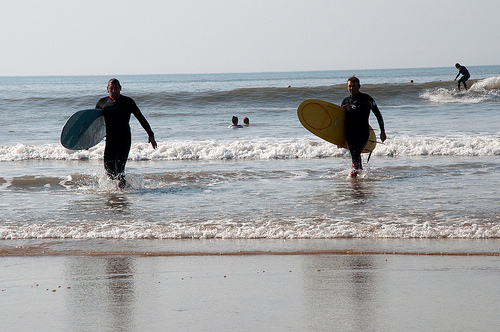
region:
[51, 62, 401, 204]
Two surfers holding their surfboards on the sea shore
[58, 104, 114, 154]
a blue surfboard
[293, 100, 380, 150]
a yellow surfboard with a red ring around it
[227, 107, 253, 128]
two people swimming in the ocean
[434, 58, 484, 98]
a surfer in the ocean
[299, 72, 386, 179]
a man in a wetsuit holding a surfboard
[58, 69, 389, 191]
two people holding surfboards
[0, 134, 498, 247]
two waves in the ocean crashing onto the shore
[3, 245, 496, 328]
wet sand on the beach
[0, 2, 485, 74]
gray sky above the ocean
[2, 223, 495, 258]
water flowing onto the beach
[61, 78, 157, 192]
surfer wearing a black wetsuit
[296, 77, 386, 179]
surfer wearing a black wetsuit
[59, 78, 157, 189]
surfer packing a blue surfboard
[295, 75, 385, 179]
surfer packing a yellow surfboard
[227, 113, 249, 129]
two people floating in ocean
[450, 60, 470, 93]
surfer riding a wave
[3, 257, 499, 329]
wet sand on shore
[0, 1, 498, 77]
hazy grey sky above the ocean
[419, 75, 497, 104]
wake from surfboard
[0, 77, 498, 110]
a wave in the ocean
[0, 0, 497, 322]
a scene outside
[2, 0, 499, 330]
a scene at an ocean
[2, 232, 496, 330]
a wet sandy shoreline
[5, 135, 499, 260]
a couple of waves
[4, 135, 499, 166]
a white wave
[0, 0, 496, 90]
a white sky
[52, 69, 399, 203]
a couple of surfers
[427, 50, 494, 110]
a surfer on a wave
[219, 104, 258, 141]
a couple of people's heads out of the water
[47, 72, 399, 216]
Two surfers holding their boards on a seas shore